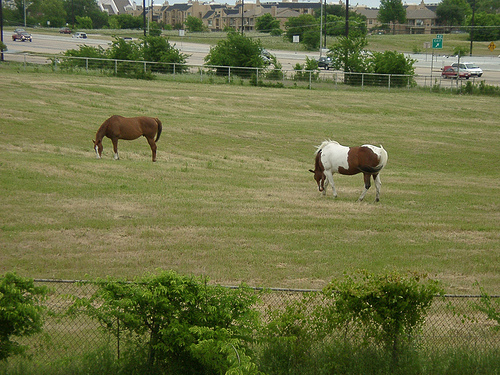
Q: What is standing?
A: Animals.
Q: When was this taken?
A: During the daytime.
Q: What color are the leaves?
A: Green.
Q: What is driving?
A: Vehicles.